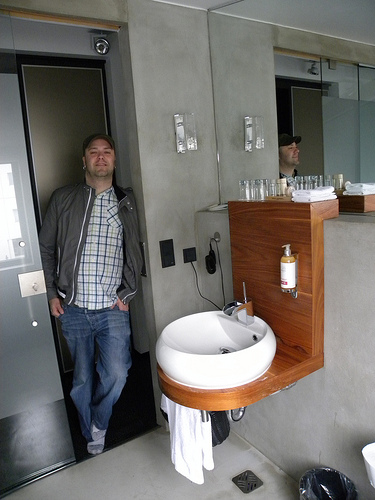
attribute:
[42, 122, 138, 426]
man — standing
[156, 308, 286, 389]
sink — white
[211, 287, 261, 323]
faucet — silver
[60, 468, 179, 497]
floor — gray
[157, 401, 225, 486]
towels — white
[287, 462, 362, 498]
can — black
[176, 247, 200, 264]
socket — black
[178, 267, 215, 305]
wire — black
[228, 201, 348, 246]
shelf — wooden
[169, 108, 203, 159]
light — off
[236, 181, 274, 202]
glasses — clear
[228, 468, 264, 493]
drain — silver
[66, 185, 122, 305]
shirt — plaid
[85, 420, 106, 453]
socks — white, grey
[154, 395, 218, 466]
towel — white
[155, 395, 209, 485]
towel — white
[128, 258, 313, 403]
sink — white, round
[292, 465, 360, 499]
garbage can — black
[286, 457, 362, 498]
trash can — black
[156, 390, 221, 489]
hand towel — white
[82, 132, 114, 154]
cap — green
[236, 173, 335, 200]
cups — glass, numerous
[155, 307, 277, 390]
bowl — big, white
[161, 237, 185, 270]
switch — black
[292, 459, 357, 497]
bin — black 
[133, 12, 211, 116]
wall — gray